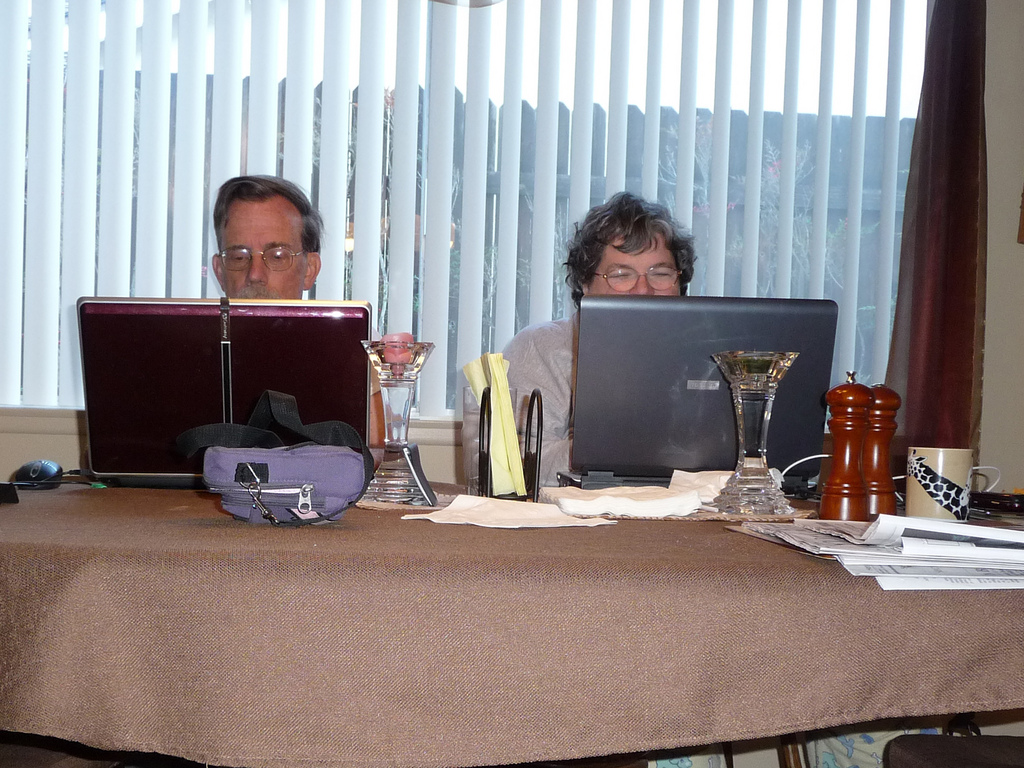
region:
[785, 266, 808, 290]
blind on the window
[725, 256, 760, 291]
blind on the window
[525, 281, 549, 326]
blind on the window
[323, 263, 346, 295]
blind on the window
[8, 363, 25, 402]
blind on the window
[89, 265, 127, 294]
blind on the window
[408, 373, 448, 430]
blind on the window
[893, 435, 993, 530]
Mug on a table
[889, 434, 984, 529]
Mug is on a table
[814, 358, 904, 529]
Salt and pepper grinders on a table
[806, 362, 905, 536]
Salt and pepper grinders are on a table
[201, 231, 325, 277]
Man wearing glasses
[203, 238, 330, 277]
Man is wearing glasses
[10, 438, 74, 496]
Mouse is on a table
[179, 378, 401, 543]
Purple bag on a table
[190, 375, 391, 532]
Purple bag is on a table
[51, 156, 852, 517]
Men on laptops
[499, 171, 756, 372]
head of a person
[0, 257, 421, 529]
red item in front of man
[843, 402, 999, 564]
cup on the table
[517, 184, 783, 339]
glasses on person's head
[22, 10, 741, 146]
blinds behind the people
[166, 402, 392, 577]
object with a zipper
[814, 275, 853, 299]
blind on the window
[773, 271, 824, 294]
blind on the window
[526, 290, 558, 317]
blind on the window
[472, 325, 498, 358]
blind on the window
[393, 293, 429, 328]
blind on the window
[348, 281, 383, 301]
blind on the window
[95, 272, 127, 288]
blind on the window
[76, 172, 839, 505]
Two men using computers at a table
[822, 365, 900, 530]
Wooden pepper mill and salt shaker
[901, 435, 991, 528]
Coffee cup on the table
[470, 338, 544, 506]
Napkins in a napkin holder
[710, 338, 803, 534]
Empty glass vase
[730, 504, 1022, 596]
Newspaper on the table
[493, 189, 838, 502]
Man using a laptop computer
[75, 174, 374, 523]
Man using a laptop computer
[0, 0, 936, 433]
Vertical blinds on the window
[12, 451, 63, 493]
Black mouse on the table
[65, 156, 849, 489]
Two people looking at laptop computers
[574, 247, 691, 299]
A pair of eyeglasses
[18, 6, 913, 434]
White blinds are partly open behind the people.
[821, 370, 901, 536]
Salt and pepper shakers on the table.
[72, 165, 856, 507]
The people work on computers at the table.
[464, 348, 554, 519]
A napkin holder between the people.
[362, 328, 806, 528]
Glass candle stick holders.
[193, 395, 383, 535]
A purple pouch on the table.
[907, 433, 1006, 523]
A coffee mug on the table.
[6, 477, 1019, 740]
A tan tablecloth under the computers.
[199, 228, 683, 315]
Both people wear glasses.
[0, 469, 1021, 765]
table with a cloth covering it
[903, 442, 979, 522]
mug with a giraffe design on it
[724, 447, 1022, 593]
papers close to mug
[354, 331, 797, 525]
two heavy glass candle holders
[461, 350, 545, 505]
napkins in a black napkin holder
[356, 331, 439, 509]
small pink candle in holder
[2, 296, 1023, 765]
two large laptop computers on table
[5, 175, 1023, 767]
two people seated behind laptop computers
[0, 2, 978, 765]
vertical blinds behind seated people